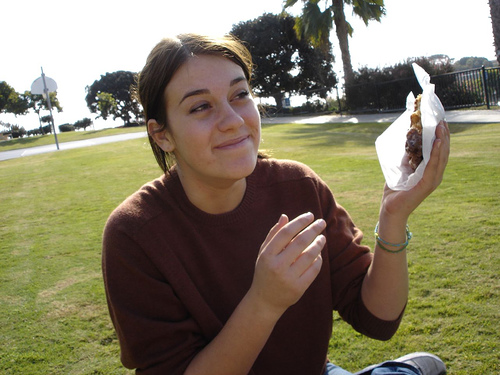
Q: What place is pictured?
A: It is a park.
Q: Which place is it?
A: It is a park.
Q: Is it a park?
A: Yes, it is a park.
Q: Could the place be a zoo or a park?
A: It is a park.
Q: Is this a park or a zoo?
A: It is a park.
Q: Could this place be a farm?
A: No, it is a park.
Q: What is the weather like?
A: It is clear.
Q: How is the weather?
A: It is clear.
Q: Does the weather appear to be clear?
A: Yes, it is clear.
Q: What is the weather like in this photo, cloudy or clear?
A: It is clear.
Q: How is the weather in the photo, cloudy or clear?
A: It is clear.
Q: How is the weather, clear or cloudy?
A: It is clear.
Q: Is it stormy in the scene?
A: No, it is clear.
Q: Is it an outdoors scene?
A: Yes, it is outdoors.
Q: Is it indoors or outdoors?
A: It is outdoors.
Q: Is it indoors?
A: No, it is outdoors.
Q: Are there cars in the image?
A: No, there are no cars.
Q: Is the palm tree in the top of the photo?
A: Yes, the palm tree is in the top of the image.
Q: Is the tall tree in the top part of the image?
A: Yes, the palm tree is in the top of the image.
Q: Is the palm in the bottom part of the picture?
A: No, the palm is in the top of the image.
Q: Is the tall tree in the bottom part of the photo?
A: No, the palm is in the top of the image.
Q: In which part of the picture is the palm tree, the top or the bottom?
A: The palm tree is in the top of the image.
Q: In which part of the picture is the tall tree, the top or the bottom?
A: The palm tree is in the top of the image.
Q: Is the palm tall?
A: Yes, the palm is tall.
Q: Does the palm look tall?
A: Yes, the palm is tall.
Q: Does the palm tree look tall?
A: Yes, the palm tree is tall.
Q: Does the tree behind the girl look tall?
A: Yes, the palm tree is tall.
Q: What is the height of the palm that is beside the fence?
A: The palm tree is tall.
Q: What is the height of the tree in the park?
A: The palm tree is tall.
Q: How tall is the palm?
A: The palm is tall.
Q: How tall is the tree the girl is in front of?
A: The palm is tall.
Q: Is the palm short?
A: No, the palm is tall.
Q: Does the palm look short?
A: No, the palm is tall.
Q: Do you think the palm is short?
A: No, the palm is tall.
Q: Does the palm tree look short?
A: No, the palm tree is tall.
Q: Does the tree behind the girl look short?
A: No, the palm tree is tall.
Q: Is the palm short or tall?
A: The palm is tall.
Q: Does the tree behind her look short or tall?
A: The palm is tall.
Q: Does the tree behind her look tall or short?
A: The palm is tall.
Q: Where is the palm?
A: The palm is in the park.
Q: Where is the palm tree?
A: The palm is in the park.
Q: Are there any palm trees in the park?
A: Yes, there is a palm tree in the park.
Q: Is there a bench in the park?
A: No, there is a palm tree in the park.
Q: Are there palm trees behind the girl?
A: Yes, there is a palm tree behind the girl.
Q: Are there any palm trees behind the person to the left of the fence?
A: Yes, there is a palm tree behind the girl.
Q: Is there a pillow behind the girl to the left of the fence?
A: No, there is a palm tree behind the girl.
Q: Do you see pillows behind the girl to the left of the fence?
A: No, there is a palm tree behind the girl.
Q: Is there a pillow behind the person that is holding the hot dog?
A: No, there is a palm tree behind the girl.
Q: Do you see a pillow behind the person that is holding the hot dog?
A: No, there is a palm tree behind the girl.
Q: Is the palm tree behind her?
A: Yes, the palm tree is behind the girl.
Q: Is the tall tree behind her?
A: Yes, the palm tree is behind the girl.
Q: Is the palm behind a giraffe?
A: No, the palm is behind the girl.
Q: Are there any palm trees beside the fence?
A: Yes, there is a palm tree beside the fence.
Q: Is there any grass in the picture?
A: Yes, there is grass.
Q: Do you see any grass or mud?
A: Yes, there is grass.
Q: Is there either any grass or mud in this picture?
A: Yes, there is grass.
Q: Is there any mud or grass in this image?
A: Yes, there is grass.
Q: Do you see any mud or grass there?
A: Yes, there is grass.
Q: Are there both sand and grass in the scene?
A: No, there is grass but no sand.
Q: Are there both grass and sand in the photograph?
A: No, there is grass but no sand.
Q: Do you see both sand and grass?
A: No, there is grass but no sand.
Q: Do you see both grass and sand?
A: No, there is grass but no sand.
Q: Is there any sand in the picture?
A: No, there is no sand.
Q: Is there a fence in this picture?
A: Yes, there is a fence.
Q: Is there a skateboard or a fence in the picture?
A: Yes, there is a fence.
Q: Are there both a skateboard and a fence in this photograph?
A: No, there is a fence but no skateboards.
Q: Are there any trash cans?
A: No, there are no trash cans.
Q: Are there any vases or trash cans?
A: No, there are no trash cans or vases.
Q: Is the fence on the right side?
A: Yes, the fence is on the right of the image.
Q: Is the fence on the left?
A: No, the fence is on the right of the image.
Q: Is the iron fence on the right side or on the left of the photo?
A: The fence is on the right of the image.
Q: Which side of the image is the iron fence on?
A: The fence is on the right of the image.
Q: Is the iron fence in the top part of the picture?
A: Yes, the fence is in the top of the image.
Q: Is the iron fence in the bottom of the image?
A: No, the fence is in the top of the image.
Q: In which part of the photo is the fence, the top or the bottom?
A: The fence is in the top of the image.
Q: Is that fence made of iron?
A: Yes, the fence is made of iron.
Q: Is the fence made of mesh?
A: No, the fence is made of iron.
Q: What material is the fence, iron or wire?
A: The fence is made of iron.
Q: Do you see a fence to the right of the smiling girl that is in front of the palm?
A: Yes, there is a fence to the right of the girl.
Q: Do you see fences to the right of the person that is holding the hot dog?
A: Yes, there is a fence to the right of the girl.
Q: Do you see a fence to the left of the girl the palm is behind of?
A: No, the fence is to the right of the girl.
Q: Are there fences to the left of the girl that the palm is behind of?
A: No, the fence is to the right of the girl.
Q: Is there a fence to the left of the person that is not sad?
A: No, the fence is to the right of the girl.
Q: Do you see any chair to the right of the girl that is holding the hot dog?
A: No, there is a fence to the right of the girl.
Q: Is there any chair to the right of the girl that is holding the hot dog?
A: No, there is a fence to the right of the girl.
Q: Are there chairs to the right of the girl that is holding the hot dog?
A: No, there is a fence to the right of the girl.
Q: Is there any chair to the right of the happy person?
A: No, there is a fence to the right of the girl.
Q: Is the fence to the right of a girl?
A: Yes, the fence is to the right of a girl.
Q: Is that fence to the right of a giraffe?
A: No, the fence is to the right of a girl.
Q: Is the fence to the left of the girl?
A: No, the fence is to the right of the girl.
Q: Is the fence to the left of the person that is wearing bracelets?
A: No, the fence is to the right of the girl.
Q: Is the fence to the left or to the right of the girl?
A: The fence is to the right of the girl.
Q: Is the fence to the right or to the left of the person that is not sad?
A: The fence is to the right of the girl.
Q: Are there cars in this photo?
A: No, there are no cars.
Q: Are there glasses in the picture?
A: No, there are no glasses.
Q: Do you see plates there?
A: No, there are no plates.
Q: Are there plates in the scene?
A: No, there are no plates.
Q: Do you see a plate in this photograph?
A: No, there are no plates.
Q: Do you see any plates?
A: No, there are no plates.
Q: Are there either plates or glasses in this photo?
A: No, there are no plates or glasses.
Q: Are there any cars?
A: No, there are no cars.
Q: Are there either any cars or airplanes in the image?
A: No, there are no cars or airplanes.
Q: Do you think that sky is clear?
A: Yes, the sky is clear.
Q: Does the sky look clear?
A: Yes, the sky is clear.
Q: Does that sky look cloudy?
A: No, the sky is clear.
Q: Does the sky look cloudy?
A: No, the sky is clear.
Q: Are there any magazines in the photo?
A: No, there are no magazines.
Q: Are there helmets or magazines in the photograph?
A: No, there are no magazines or helmets.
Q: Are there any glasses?
A: No, there are no glasses.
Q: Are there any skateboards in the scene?
A: No, there are no skateboards.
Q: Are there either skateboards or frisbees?
A: No, there are no skateboards or frisbees.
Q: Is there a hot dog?
A: Yes, there is a hot dog.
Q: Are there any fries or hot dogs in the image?
A: Yes, there is a hot dog.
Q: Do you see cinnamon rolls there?
A: No, there are no cinnamon rolls.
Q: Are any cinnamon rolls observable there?
A: No, there are no cinnamon rolls.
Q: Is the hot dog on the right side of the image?
A: Yes, the hot dog is on the right of the image.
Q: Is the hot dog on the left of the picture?
A: No, the hot dog is on the right of the image.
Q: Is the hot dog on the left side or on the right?
A: The hot dog is on the right of the image.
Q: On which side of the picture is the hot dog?
A: The hot dog is on the right of the image.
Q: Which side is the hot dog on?
A: The hot dog is on the right of the image.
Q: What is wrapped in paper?
A: The hot dog is wrapped in paper.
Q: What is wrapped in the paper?
A: The hot dog is wrapped in paper.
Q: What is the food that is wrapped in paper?
A: The food is a hot dog.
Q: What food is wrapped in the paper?
A: The food is a hot dog.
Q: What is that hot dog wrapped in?
A: The hot dog is wrapped in paper.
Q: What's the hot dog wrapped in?
A: The hot dog is wrapped in paper.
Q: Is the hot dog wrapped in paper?
A: Yes, the hot dog is wrapped in paper.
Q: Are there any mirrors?
A: No, there are no mirrors.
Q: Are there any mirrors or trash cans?
A: No, there are no mirrors or trash cans.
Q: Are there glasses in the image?
A: No, there are no glasses.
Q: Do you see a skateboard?
A: No, there are no skateboards.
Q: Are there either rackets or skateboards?
A: No, there are no skateboards or rackets.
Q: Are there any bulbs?
A: No, there are no bulbs.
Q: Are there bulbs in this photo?
A: No, there are no bulbs.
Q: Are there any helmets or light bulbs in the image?
A: No, there are no light bulbs or helmets.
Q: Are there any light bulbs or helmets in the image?
A: No, there are no light bulbs or helmets.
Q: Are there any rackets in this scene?
A: No, there are no rackets.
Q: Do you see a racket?
A: No, there are no rackets.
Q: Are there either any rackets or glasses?
A: No, there are no rackets or glasses.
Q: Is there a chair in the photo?
A: No, there are no chairs.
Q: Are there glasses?
A: No, there are no glasses.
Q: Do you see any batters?
A: No, there are no batters.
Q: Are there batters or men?
A: No, there are no batters or men.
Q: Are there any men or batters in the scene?
A: No, there are no batters or men.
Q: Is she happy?
A: Yes, the girl is happy.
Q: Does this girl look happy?
A: Yes, the girl is happy.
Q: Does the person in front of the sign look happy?
A: Yes, the girl is happy.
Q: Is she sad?
A: No, the girl is happy.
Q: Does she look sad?
A: No, the girl is happy.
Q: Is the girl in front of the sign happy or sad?
A: The girl is happy.